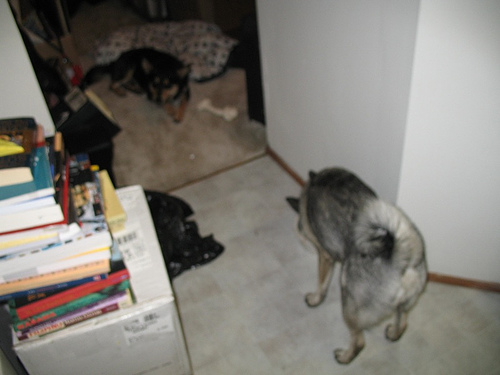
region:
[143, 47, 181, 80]
the dog is black in color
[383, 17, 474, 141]
this is the wall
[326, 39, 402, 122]
the wall is white in color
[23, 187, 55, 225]
this is a book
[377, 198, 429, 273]
this is the tail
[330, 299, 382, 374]
this is the leg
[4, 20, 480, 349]
animals in a scene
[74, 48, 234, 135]
a dog in a closet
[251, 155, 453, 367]
a dog by the wall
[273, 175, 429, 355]
this dog is gray and black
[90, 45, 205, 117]
this dog is black with brown trim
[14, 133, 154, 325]
books on a box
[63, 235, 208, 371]
the box is white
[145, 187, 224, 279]
a black object on the floor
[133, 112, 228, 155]
tan carpet beneath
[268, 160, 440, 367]
dog standing in the floor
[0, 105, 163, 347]
books kept in the rack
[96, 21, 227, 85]
pillow in the floor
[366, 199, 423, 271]
tail of the dog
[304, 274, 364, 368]
legs of the dog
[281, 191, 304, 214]
ear of the dog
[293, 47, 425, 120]
white color wall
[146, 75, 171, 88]
eyes of the dog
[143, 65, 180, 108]
head of the dog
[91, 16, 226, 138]
a dog laying on the floor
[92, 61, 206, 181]
a dog laying on the floor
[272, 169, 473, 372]
the dog is grey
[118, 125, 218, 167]
the floor is carpeted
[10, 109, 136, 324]
books are on the box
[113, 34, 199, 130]
the dog is black and brown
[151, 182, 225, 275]
black paperbag is on the ground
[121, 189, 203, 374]
the cartoon box is white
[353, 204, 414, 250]
the tail is curled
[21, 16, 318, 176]
the door is open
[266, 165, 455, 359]
the dog is looking down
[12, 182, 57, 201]
the book is blue